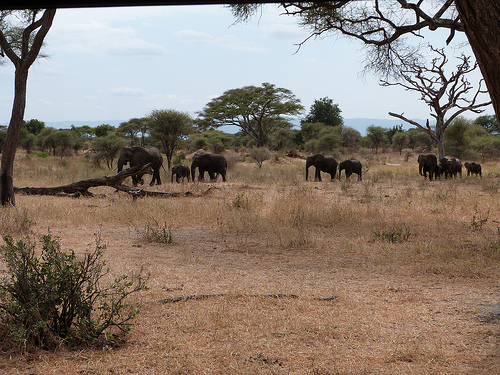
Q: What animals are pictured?
A: Elephants.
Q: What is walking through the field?
A: A herd of elephants.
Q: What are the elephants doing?
A: Walking.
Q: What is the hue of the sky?
A: Light blue.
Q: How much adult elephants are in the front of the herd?
A: Two.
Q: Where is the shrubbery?
A: On the ground.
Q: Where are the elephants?
A: Safari.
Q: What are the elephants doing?
A: Walking.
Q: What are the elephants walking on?
A: Grass.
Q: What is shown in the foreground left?
A: Bush.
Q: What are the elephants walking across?
A: Field.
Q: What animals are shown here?
A: Elephants.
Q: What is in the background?
A: Trees.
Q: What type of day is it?
A: Sunny.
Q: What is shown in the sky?
A: Clouds.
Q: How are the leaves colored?
A: Green.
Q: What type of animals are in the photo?
A: Elephant.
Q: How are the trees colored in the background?
A: Green.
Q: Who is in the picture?
A: Elephants.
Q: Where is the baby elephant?
A: Between two adults.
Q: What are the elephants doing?
A: Walking.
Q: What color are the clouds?
A: White.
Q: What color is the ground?
A: Brown.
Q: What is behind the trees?
A: Mountains.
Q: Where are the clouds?
A: In the sky.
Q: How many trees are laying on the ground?
A: One.